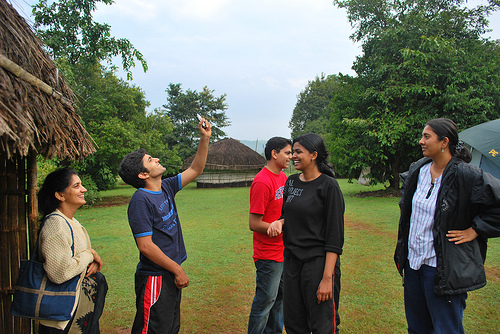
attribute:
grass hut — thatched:
[181, 136, 268, 170]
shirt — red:
[245, 165, 282, 261]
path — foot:
[342, 209, 399, 246]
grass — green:
[197, 189, 242, 269]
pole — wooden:
[0, 130, 12, 330]